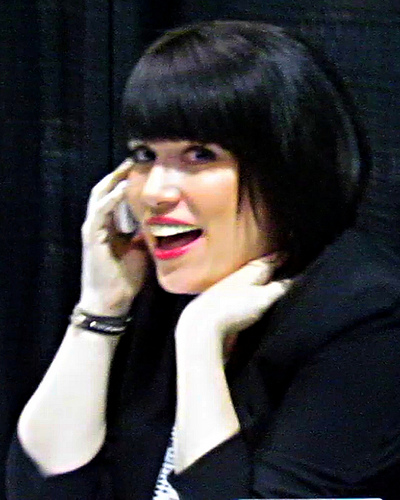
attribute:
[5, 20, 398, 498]
woman — arm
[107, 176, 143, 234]
phone — cell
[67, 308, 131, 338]
band — black, silver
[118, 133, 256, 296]
face — womans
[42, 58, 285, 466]
woman — white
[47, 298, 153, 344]
bracelet — gray, black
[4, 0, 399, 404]
background — black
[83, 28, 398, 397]
person — smiling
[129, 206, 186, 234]
lipstick — bright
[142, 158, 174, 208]
nose — womans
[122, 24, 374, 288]
haircut — dark, short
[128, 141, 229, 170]
eyes — womans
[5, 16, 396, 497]
woman's — wrist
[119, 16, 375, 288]
hair — black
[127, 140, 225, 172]
eyes — blue